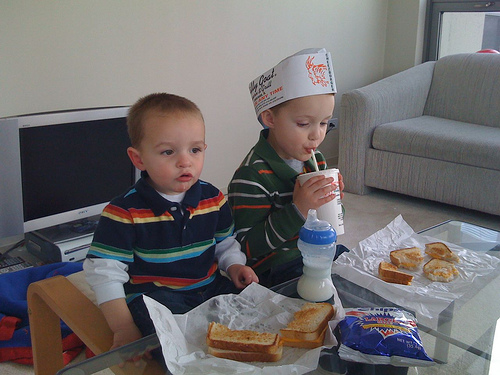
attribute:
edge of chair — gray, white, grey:
[336, 50, 498, 220]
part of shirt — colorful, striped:
[80, 172, 251, 308]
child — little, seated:
[81, 91, 262, 369]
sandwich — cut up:
[378, 260, 414, 289]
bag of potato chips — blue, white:
[338, 304, 437, 369]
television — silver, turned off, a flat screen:
[1, 104, 143, 240]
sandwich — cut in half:
[201, 295, 335, 365]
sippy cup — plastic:
[296, 208, 337, 304]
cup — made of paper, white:
[297, 164, 343, 237]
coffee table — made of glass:
[56, 217, 499, 375]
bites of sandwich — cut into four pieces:
[371, 240, 461, 288]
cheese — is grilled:
[377, 271, 413, 283]